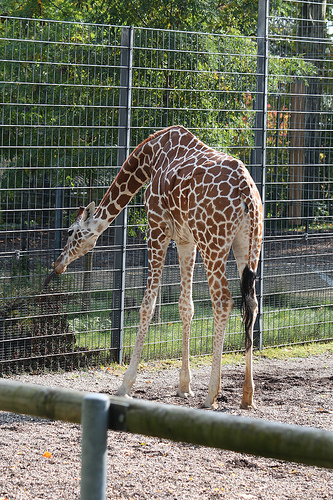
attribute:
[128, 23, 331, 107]
metal fence — large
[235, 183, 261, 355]
tail — large, black, hairy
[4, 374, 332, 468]
pole — wooden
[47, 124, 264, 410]
giraffe — standing, big 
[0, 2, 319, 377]
fence — gray , metal 